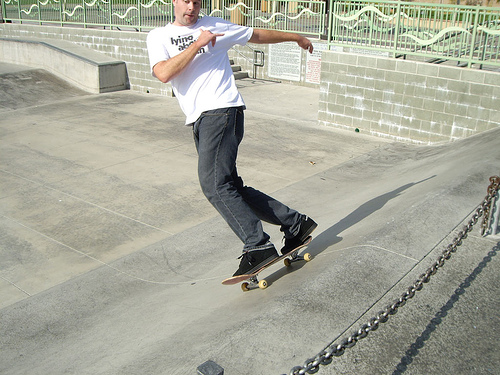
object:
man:
[139, 0, 318, 264]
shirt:
[145, 15, 254, 114]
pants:
[192, 105, 303, 258]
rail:
[1, 0, 500, 53]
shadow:
[248, 171, 438, 293]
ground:
[0, 64, 498, 375]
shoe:
[226, 245, 280, 277]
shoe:
[279, 214, 318, 255]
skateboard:
[221, 233, 315, 289]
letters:
[169, 37, 176, 45]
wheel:
[240, 282, 250, 291]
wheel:
[257, 280, 269, 290]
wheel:
[282, 258, 293, 266]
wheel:
[302, 252, 312, 262]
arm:
[145, 29, 224, 80]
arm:
[216, 23, 313, 55]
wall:
[0, 19, 496, 133]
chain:
[277, 191, 497, 372]